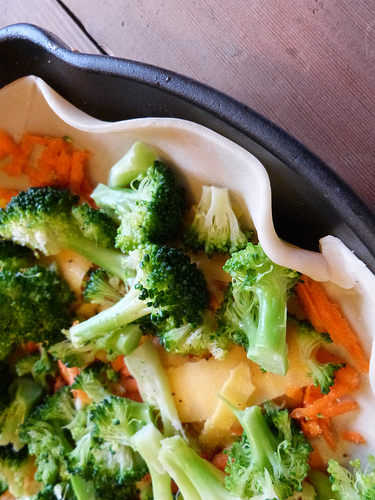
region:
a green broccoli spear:
[65, 245, 197, 350]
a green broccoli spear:
[217, 399, 300, 494]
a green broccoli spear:
[228, 245, 292, 372]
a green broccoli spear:
[71, 392, 167, 483]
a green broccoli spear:
[3, 184, 77, 255]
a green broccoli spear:
[1, 255, 66, 361]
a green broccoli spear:
[7, 378, 87, 491]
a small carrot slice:
[290, 279, 363, 369]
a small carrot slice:
[291, 374, 349, 421]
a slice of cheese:
[149, 345, 301, 410]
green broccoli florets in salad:
[85, 158, 170, 246]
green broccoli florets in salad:
[12, 259, 72, 340]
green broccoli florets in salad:
[78, 233, 185, 332]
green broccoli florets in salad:
[16, 367, 125, 478]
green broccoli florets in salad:
[115, 416, 208, 491]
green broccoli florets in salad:
[222, 401, 299, 496]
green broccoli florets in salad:
[223, 247, 285, 372]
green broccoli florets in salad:
[182, 181, 245, 254]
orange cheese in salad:
[192, 362, 248, 407]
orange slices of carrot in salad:
[6, 121, 74, 183]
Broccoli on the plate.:
[55, 136, 281, 349]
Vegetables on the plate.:
[38, 152, 368, 373]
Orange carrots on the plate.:
[227, 360, 350, 454]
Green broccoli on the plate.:
[61, 260, 270, 378]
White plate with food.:
[53, 88, 331, 273]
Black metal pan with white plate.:
[49, 23, 304, 197]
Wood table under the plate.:
[91, 3, 371, 171]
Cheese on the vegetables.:
[88, 294, 325, 462]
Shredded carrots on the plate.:
[35, 128, 154, 228]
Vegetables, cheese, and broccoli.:
[20, 169, 341, 416]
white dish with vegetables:
[5, 82, 346, 497]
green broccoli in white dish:
[89, 110, 316, 295]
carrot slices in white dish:
[293, 258, 370, 401]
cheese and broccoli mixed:
[149, 312, 363, 484]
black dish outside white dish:
[63, 35, 320, 230]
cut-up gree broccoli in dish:
[41, 146, 219, 362]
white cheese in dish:
[185, 359, 373, 415]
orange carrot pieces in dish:
[20, 139, 120, 203]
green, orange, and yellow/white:
[82, 241, 251, 444]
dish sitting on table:
[60, 6, 340, 330]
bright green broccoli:
[10, 130, 348, 485]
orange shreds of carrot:
[281, 253, 365, 391]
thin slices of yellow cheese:
[141, 316, 310, 436]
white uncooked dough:
[33, 49, 361, 305]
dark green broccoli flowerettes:
[134, 237, 218, 320]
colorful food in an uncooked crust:
[13, 167, 345, 486]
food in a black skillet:
[5, 6, 365, 309]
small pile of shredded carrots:
[4, 126, 105, 220]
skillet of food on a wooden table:
[10, 4, 370, 447]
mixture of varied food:
[7, 168, 342, 488]